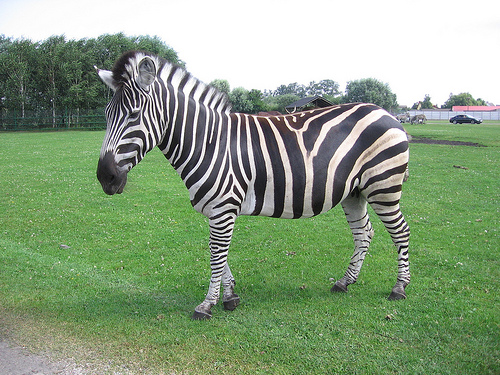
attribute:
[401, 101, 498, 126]
wall — white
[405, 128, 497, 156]
soil — sandy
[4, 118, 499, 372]
ground — large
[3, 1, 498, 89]
sky — white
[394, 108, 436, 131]
elephants — sitting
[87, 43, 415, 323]
zebra — majestic, black, white, looking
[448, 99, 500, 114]
roof — red, here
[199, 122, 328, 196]
stripes — black, white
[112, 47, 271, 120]
mane — black, white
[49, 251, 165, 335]
grass — short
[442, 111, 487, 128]
car — moving, driving, black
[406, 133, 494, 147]
ditch — brown, here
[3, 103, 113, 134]
fence — blue